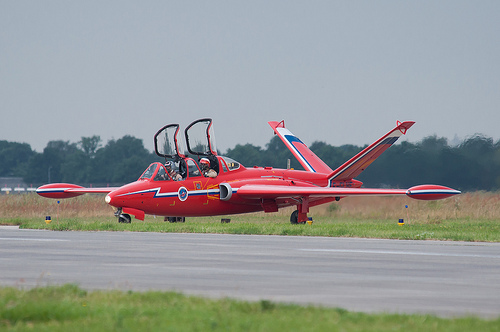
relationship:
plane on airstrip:
[0, 105, 461, 210] [141, 237, 203, 254]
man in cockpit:
[165, 161, 182, 181] [151, 119, 180, 185]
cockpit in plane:
[151, 119, 180, 185] [0, 105, 461, 210]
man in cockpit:
[200, 157, 217, 177] [190, 119, 217, 186]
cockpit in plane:
[190, 119, 217, 186] [0, 105, 461, 210]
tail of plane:
[259, 113, 417, 172] [0, 105, 461, 210]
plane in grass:
[0, 105, 461, 210] [45, 292, 80, 313]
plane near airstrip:
[0, 105, 461, 210] [141, 237, 203, 254]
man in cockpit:
[156, 155, 175, 179] [151, 119, 180, 185]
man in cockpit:
[189, 150, 213, 181] [190, 119, 217, 186]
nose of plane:
[96, 181, 130, 218] [0, 105, 461, 210]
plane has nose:
[0, 105, 461, 210] [96, 181, 130, 218]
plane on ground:
[0, 105, 461, 210] [159, 230, 383, 234]